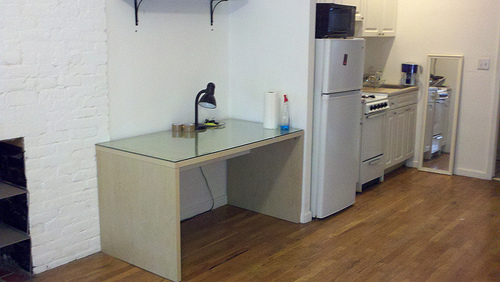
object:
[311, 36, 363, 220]
refrigerator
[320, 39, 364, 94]
freezer door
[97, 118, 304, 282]
desk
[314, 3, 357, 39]
microwave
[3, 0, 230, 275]
wall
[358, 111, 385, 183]
oven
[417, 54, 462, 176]
mirror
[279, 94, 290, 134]
cleaner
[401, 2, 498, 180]
wall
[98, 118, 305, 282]
white desk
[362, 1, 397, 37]
cabinet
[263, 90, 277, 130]
paper towel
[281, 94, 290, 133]
bottle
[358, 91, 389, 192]
gas stove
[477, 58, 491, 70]
electrical receptacle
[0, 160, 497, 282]
floor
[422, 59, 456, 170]
glass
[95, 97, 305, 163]
glass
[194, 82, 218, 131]
lamp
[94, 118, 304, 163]
top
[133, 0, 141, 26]
shelf bracket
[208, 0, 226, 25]
shelf bracket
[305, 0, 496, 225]
kitchen